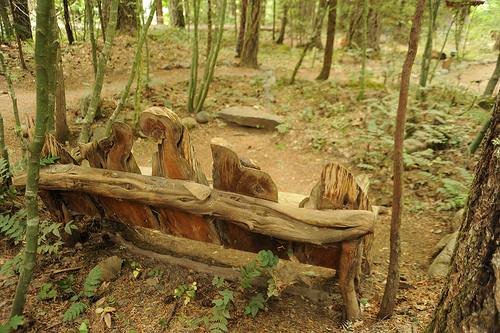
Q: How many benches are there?
A: One.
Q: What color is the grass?
A: Green.